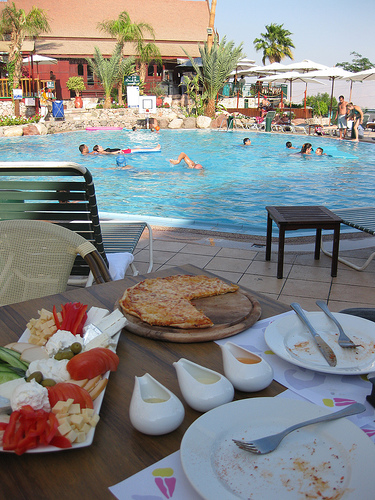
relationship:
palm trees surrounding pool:
[3, 3, 292, 109] [2, 121, 373, 238]